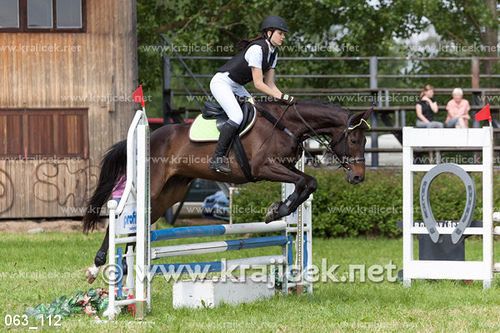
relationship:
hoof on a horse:
[81, 265, 103, 285] [72, 92, 364, 267]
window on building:
[55, 2, 82, 27] [2, 2, 144, 228]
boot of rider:
[209, 121, 240, 171] [205, 16, 295, 176]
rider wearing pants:
[205, 16, 295, 176] [206, 54, 278, 120]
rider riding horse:
[205, 16, 295, 176] [80, 95, 375, 286]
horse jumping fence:
[81, 80, 391, 229] [103, 109, 313, 321]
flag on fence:
[131, 85, 146, 105] [103, 109, 313, 321]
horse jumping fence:
[80, 95, 375, 286] [106, 86, 313, 321]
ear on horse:
[343, 105, 363, 129] [80, 95, 375, 286]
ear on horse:
[364, 103, 377, 123] [80, 95, 375, 286]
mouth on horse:
[344, 166, 367, 185] [81, 95, 368, 302]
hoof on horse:
[263, 200, 291, 225] [81, 95, 368, 302]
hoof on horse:
[292, 174, 324, 217] [81, 95, 368, 302]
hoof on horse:
[92, 244, 112, 265] [80, 95, 375, 286]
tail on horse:
[78, 140, 126, 235] [80, 95, 375, 286]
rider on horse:
[208, 7, 294, 171] [80, 95, 375, 286]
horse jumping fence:
[80, 95, 375, 286] [103, 109, 313, 321]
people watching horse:
[407, 80, 481, 127] [84, 114, 370, 271]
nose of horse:
[344, 154, 363, 190] [164, 95, 471, 204]